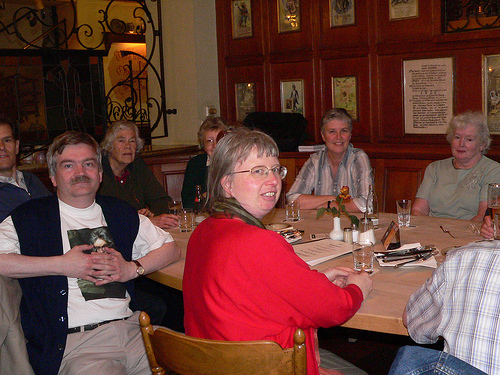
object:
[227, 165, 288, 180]
glasses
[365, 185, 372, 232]
shaker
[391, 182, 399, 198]
ground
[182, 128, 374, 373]
woman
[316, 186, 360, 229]
flowers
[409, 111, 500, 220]
woman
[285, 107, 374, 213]
woman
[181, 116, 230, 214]
woman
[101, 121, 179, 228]
woman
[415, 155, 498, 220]
green shirt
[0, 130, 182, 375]
man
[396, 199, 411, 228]
glass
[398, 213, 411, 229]
liquid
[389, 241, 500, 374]
person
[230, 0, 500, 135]
pictures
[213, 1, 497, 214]
wall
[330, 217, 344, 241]
vase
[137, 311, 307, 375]
wooden chair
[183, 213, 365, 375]
red shirt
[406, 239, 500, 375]
plaid shirt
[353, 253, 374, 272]
water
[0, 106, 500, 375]
people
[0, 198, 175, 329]
vest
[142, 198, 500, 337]
table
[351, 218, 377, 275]
salt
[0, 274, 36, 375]
chair